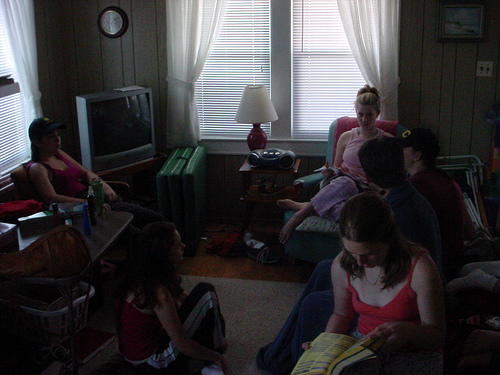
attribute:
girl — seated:
[277, 90, 397, 245]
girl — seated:
[109, 221, 230, 365]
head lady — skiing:
[325, 191, 402, 296]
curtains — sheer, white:
[153, 0, 398, 150]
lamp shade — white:
[230, 81, 279, 124]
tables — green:
[157, 142, 213, 262]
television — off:
[73, 85, 155, 170]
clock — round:
[93, 5, 130, 39]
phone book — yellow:
[293, 329, 395, 374]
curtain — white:
[164, 0, 224, 145]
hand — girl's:
[368, 320, 405, 346]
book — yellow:
[306, 320, 398, 368]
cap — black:
[23, 110, 71, 147]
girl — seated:
[93, 211, 248, 373]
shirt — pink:
[340, 120, 388, 182]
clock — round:
[97, 8, 126, 36]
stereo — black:
[242, 144, 346, 192]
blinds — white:
[194, 0, 359, 137]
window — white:
[162, 3, 400, 150]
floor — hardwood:
[170, 196, 322, 306]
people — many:
[11, 35, 476, 362]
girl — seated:
[267, 73, 408, 258]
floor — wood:
[176, 229, 311, 281]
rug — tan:
[80, 272, 308, 373]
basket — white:
[20, 272, 106, 350]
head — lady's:
[25, 113, 65, 166]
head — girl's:
[121, 217, 201, 285]